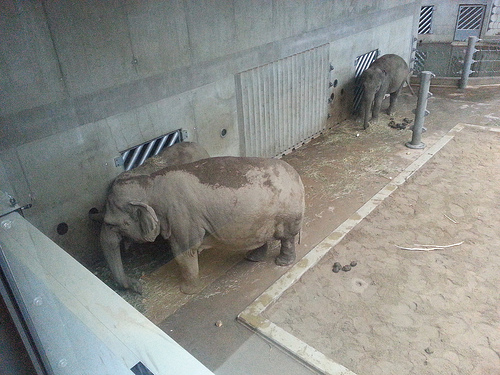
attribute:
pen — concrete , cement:
[2, 7, 485, 367]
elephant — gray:
[72, 140, 352, 314]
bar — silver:
[124, 123, 194, 175]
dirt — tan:
[260, 126, 497, 373]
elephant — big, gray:
[62, 127, 359, 312]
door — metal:
[229, 35, 344, 162]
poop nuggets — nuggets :
[325, 255, 360, 277]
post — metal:
[403, 70, 436, 150]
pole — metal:
[410, 70, 440, 148]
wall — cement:
[2, 202, 214, 373]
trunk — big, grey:
[99, 225, 148, 295]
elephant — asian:
[93, 150, 312, 294]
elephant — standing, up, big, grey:
[100, 155, 305, 296]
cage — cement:
[35, 42, 454, 296]